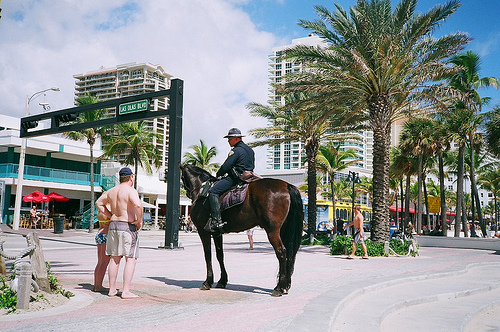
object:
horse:
[178, 161, 303, 296]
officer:
[207, 127, 255, 229]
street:
[313, 255, 488, 332]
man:
[95, 167, 144, 298]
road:
[36, 226, 88, 255]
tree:
[269, 0, 469, 255]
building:
[72, 61, 174, 164]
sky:
[105, 2, 259, 57]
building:
[266, 33, 384, 173]